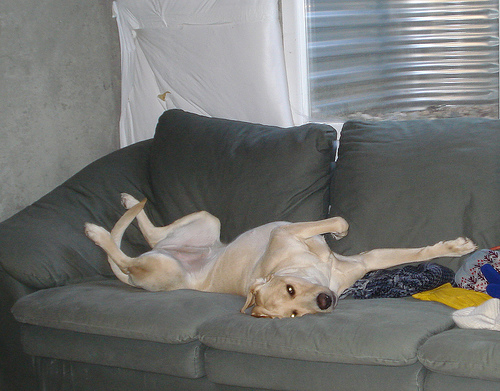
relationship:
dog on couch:
[84, 191, 479, 318] [1, 108, 496, 390]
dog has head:
[84, 191, 479, 318] [241, 274, 336, 319]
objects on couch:
[343, 260, 489, 314] [1, 108, 496, 390]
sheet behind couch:
[112, 4, 310, 149] [1, 108, 496, 390]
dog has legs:
[84, 191, 479, 318] [83, 190, 478, 271]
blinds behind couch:
[307, 2, 500, 124] [1, 108, 496, 390]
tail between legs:
[104, 196, 146, 283] [85, 190, 220, 292]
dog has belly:
[84, 191, 479, 318] [176, 224, 253, 279]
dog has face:
[84, 191, 479, 318] [248, 266, 337, 319]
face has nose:
[248, 266, 337, 319] [317, 292, 333, 311]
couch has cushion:
[1, 108, 496, 390] [12, 278, 246, 389]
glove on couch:
[413, 283, 490, 311] [1, 108, 496, 390]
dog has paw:
[84, 191, 479, 318] [328, 220, 350, 240]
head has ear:
[241, 274, 336, 319] [239, 279, 264, 314]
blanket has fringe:
[334, 261, 452, 300] [343, 275, 378, 303]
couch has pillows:
[1, 108, 496, 390] [150, 108, 499, 255]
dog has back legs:
[84, 191, 479, 318] [85, 190, 220, 292]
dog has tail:
[84, 191, 479, 318] [104, 196, 146, 283]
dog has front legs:
[84, 191, 479, 318] [265, 216, 480, 281]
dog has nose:
[84, 191, 479, 318] [317, 292, 333, 311]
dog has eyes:
[84, 191, 479, 318] [285, 284, 299, 317]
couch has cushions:
[1, 108, 496, 390] [8, 275, 498, 390]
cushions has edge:
[11, 286, 495, 389] [11, 288, 494, 390]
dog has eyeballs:
[84, 191, 479, 318] [287, 285, 301, 317]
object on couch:
[453, 298, 498, 332] [1, 108, 496, 390]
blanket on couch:
[334, 261, 452, 300] [1, 108, 496, 390]